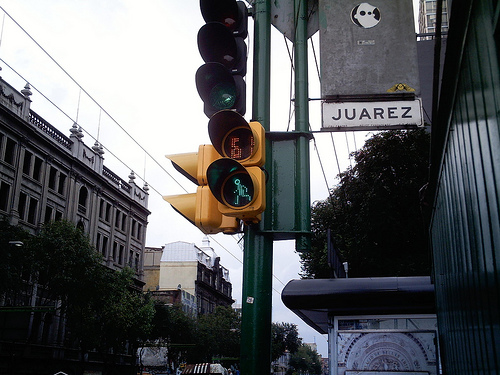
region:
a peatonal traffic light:
[158, 109, 277, 250]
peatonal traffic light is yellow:
[162, 107, 272, 248]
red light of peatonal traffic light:
[197, 106, 262, 161]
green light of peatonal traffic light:
[200, 156, 262, 212]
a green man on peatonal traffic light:
[225, 171, 255, 211]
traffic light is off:
[188, 1, 258, 124]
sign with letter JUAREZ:
[315, 90, 423, 135]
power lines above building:
[0, 16, 172, 223]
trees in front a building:
[0, 70, 162, 365]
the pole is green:
[245, 0, 285, 372]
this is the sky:
[115, 11, 151, 45]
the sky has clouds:
[128, 29, 171, 62]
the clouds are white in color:
[126, 38, 178, 91]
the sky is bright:
[89, 17, 164, 75]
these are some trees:
[14, 234, 213, 357]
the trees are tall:
[45, 237, 220, 367]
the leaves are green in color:
[62, 242, 106, 286]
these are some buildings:
[7, 87, 178, 272]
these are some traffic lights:
[164, 115, 261, 212]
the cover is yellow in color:
[193, 200, 214, 212]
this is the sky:
[136, 19, 172, 69]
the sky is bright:
[125, 13, 176, 80]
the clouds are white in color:
[130, 64, 189, 111]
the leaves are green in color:
[85, 283, 145, 316]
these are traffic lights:
[165, 12, 270, 224]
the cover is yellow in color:
[199, 196, 219, 220]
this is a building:
[18, 132, 131, 242]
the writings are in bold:
[330, 100, 410, 126]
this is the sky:
[96, 24, 171, 80]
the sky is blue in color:
[108, 21, 181, 101]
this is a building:
[9, 115, 104, 215]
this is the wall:
[14, 167, 40, 186]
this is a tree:
[46, 216, 81, 310]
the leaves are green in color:
[46, 211, 86, 268]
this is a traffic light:
[196, 28, 253, 217]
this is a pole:
[241, 228, 278, 337]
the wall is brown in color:
[162, 256, 189, 292]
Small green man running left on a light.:
[228, 177, 251, 209]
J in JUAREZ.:
[331, 108, 343, 121]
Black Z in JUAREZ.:
[401, 107, 411, 119]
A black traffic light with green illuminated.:
[197, 0, 247, 117]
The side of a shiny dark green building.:
[426, 26, 499, 374]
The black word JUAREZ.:
[332, 107, 412, 121]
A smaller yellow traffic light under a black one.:
[163, 108, 268, 233]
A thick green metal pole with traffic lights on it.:
[241, 2, 271, 373]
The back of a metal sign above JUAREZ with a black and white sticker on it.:
[317, 1, 419, 99]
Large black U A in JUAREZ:
[343, 107, 370, 120]